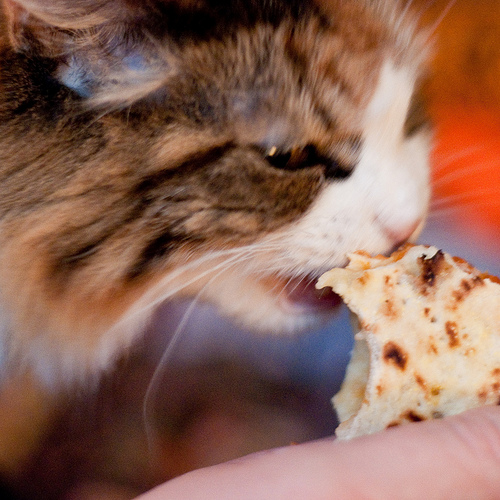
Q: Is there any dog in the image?
A: No, there are no dogs.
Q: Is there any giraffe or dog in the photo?
A: No, there are no dogs or giraffes.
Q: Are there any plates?
A: No, there are no plates.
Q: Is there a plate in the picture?
A: No, there are no plates.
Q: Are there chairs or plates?
A: No, there are no plates or chairs.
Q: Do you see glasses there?
A: No, there are no glasses.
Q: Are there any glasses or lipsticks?
A: No, there are no glasses or lipsticks.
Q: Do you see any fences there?
A: No, there are no fences.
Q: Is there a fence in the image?
A: No, there are no fences.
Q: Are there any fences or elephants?
A: No, there are no fences or elephants.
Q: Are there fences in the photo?
A: No, there are no fences.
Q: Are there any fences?
A: No, there are no fences.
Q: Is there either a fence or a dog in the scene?
A: No, there are no fences or dogs.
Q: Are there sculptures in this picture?
A: No, there are no sculptures.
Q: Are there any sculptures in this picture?
A: No, there are no sculptures.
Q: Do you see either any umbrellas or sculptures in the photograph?
A: No, there are no sculptures or umbrellas.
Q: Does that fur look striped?
A: Yes, the fur is striped.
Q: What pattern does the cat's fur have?
A: The fur has striped pattern.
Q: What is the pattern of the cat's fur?
A: The fur is striped.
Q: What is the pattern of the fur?
A: The fur is striped.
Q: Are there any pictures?
A: No, there are no pictures.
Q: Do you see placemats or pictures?
A: No, there are no pictures or placemats.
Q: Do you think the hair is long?
A: Yes, the hair is long.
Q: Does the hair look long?
A: Yes, the hair is long.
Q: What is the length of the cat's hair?
A: The hair is long.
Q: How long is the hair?
A: The hair is long.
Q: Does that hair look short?
A: No, the hair is long.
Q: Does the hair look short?
A: No, the hair is long.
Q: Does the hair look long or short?
A: The hair is long.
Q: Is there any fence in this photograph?
A: No, there are no fences.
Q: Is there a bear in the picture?
A: No, there are no bears.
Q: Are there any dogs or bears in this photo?
A: No, there are no bears or dogs.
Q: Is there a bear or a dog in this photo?
A: No, there are no bears or dogs.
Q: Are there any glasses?
A: No, there are no glasses.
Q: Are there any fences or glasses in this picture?
A: No, there are no glasses or fences.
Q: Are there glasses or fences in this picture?
A: No, there are no glasses or fences.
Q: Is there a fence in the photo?
A: No, there are no fences.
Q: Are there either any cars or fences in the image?
A: No, there are no fences or cars.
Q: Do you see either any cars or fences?
A: No, there are no fences or cars.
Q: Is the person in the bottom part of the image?
A: Yes, the person is in the bottom of the image.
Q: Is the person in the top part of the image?
A: No, the person is in the bottom of the image.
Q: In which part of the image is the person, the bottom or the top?
A: The person is in the bottom of the image.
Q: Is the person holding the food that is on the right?
A: Yes, the person is holding the food.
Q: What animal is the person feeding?
A: The person is feeding the cat.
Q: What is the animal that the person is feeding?
A: The animal is a cat.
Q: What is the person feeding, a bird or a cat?
A: The person is feeding a cat.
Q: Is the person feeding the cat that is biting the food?
A: Yes, the person is feeding the cat.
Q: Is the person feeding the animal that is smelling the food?
A: Yes, the person is feeding the cat.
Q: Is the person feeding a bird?
A: No, the person is feeding the cat.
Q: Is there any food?
A: Yes, there is food.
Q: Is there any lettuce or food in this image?
A: Yes, there is food.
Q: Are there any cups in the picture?
A: No, there are no cups.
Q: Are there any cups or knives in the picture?
A: No, there are no cups or knives.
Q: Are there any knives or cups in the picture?
A: No, there are no cups or knives.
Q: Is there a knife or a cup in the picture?
A: No, there are no cups or knives.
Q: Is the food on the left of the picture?
A: No, the food is on the right of the image.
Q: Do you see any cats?
A: Yes, there is a cat.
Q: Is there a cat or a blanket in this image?
A: Yes, there is a cat.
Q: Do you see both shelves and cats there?
A: No, there is a cat but no shelves.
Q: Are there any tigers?
A: No, there are no tigers.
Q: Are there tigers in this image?
A: No, there are no tigers.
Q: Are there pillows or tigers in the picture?
A: No, there are no tigers or pillows.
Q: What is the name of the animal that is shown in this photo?
A: The animal is a cat.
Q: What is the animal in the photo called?
A: The animal is a cat.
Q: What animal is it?
A: The animal is a cat.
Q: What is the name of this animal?
A: This is a cat.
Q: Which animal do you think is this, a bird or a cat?
A: This is a cat.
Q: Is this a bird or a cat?
A: This is a cat.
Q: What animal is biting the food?
A: The cat is biting the food.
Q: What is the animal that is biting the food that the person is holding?
A: The animal is a cat.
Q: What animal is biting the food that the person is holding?
A: The animal is a cat.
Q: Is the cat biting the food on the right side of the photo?
A: Yes, the cat is biting the food.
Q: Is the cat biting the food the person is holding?
A: Yes, the cat is biting the food.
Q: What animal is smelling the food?
A: The cat is smelling the food.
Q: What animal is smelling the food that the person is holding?
A: The animal is a cat.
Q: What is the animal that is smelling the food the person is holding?
A: The animal is a cat.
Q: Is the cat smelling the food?
A: Yes, the cat is smelling the food.